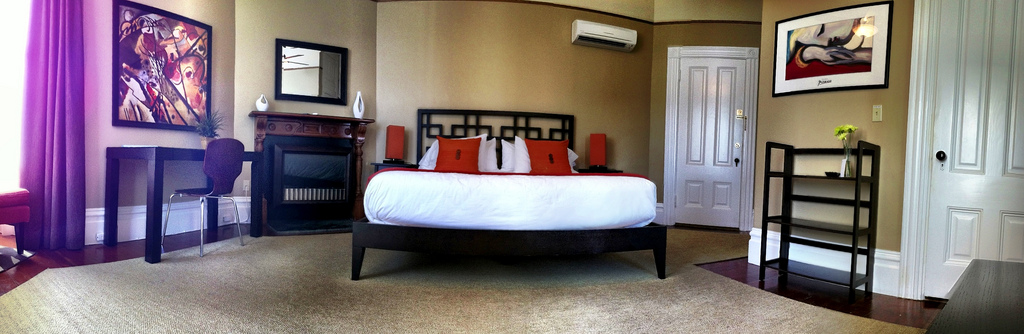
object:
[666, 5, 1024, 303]
doors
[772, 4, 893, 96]
artwork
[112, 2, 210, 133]
picture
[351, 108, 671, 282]
bed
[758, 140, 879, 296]
shelf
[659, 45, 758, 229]
door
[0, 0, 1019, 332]
room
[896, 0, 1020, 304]
door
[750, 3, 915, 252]
wall